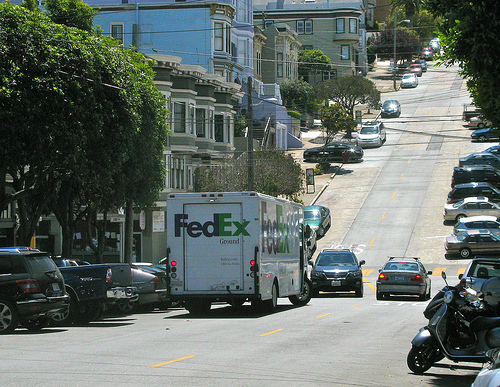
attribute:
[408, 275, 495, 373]
motorcycle — parked, moped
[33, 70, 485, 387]
street — cement, two lanes, slopped, slope, sloping, wide, grey, gray, hard, long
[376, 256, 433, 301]
car — dark, stopped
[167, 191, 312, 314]
truck — for delivery, fed ex, double parked, fed ex truck, white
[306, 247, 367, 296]
suv — black, dark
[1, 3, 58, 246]
tree — in a row, big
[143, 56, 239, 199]
home — victorian, green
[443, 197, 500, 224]
car — shiny, in a row, silver, parked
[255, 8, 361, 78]
building — beige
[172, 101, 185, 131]
window — rectangle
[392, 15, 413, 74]
streetlight — tall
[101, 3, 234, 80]
house — blue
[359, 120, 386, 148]
car — white